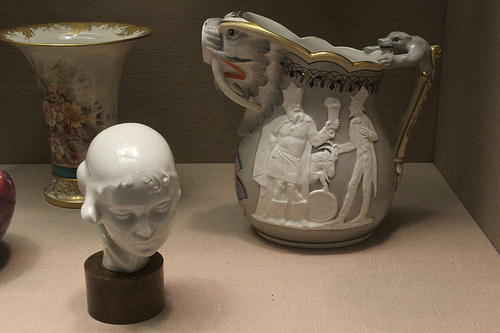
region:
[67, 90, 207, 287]
Bust on a display table.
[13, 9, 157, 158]
Vase with flowers on it.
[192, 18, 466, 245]
Very large ornate pitcher.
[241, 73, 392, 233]
Two men on the vase.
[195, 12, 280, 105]
An animal head is the spout.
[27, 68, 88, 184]
Flowers on the vase.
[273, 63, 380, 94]
Black and gold design on the vase.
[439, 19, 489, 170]
Tan wall behind the pitcher.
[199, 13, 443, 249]
An unattractive pitcher on display.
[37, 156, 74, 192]
Blue band at the bottom of the vase.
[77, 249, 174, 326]
brown base of statue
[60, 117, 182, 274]
sculpture of human face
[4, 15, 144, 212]
vase on table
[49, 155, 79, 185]
blue stripe on vase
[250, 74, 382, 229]
men on surface of vase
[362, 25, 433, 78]
monster sculpted into vase handle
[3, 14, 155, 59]
vase opening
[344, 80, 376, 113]
top hat on man on vase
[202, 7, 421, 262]
vase on the table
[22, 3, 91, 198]
vase on the table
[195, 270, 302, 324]
he table is tan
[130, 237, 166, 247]
mouth of the statue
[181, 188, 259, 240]
shadow of the vase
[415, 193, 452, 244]
shadow of the vase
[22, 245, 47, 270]
shadow of the vase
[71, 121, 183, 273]
White statue of a head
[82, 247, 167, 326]
Cylindrical brown base of a statue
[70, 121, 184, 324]
White head sculpture on a brown base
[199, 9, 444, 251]
Decorative gray pitcher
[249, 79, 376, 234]
Two white carvings on the side of a pitcher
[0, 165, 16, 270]
Part of a red vase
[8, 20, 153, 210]
Old white and gold vase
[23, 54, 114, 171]
Flower paintings on a vase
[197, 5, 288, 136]
Bird head carved into a pitcher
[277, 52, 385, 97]
Black and gold decoration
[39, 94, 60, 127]
flower painted on vase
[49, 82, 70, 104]
flower painted on vase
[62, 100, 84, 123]
flower painted on vase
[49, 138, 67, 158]
flower painted on vase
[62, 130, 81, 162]
flower painted on vase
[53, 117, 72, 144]
flower painted on vase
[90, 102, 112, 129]
flower painted on vase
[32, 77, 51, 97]
flower painted on vase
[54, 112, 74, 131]
flower painted on vase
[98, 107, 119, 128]
flower painted on vase